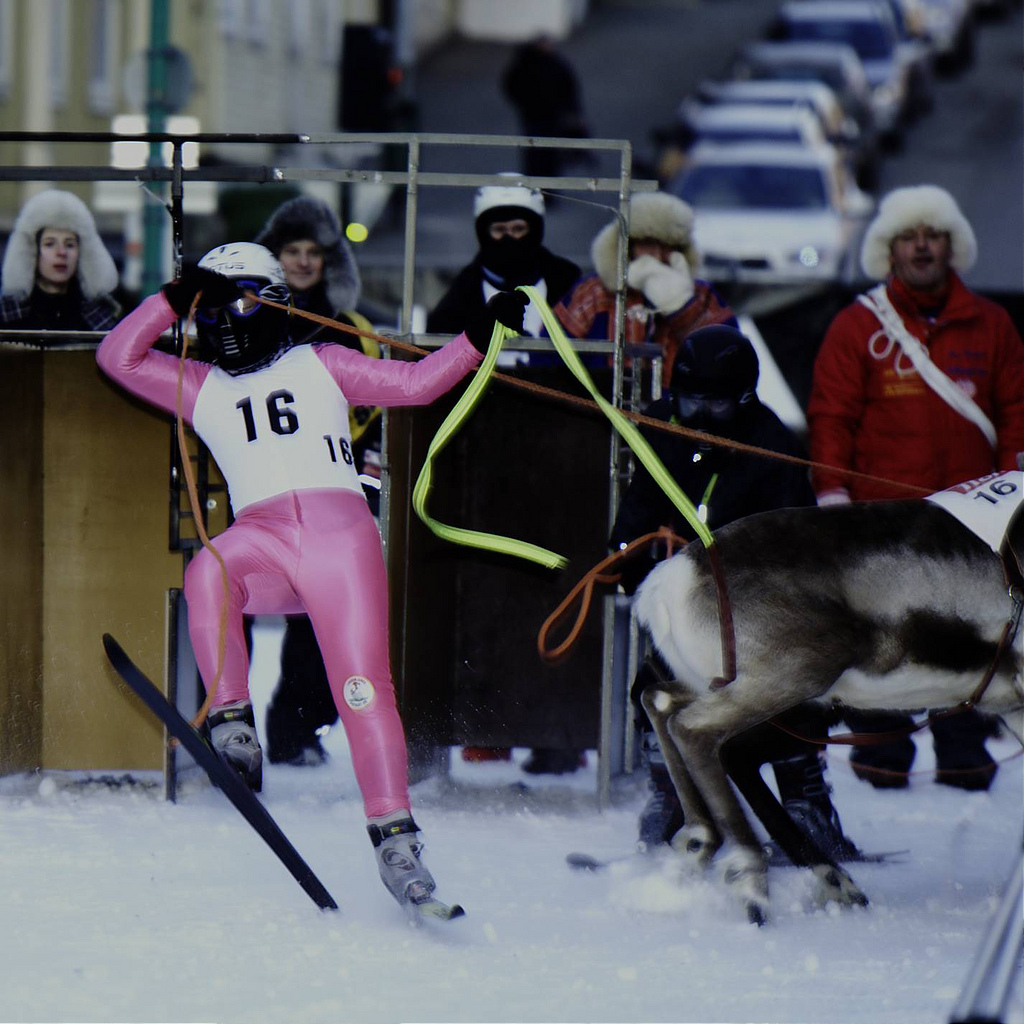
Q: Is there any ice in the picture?
A: Yes, there is ice.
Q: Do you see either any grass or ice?
A: Yes, there is ice.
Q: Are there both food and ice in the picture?
A: No, there is ice but no food.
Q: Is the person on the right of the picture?
A: Yes, the person is on the right of the image.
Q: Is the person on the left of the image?
A: No, the person is on the right of the image.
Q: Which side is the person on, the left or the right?
A: The person is on the right of the image.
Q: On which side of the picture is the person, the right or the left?
A: The person is on the right of the image.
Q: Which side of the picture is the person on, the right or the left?
A: The person is on the right of the image.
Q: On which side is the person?
A: The person is on the right of the image.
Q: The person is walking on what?
A: The person is walking on the ice.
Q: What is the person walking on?
A: The person is walking on the ice.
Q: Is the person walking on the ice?
A: Yes, the person is walking on the ice.